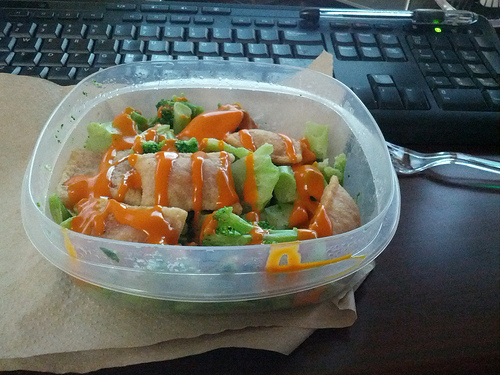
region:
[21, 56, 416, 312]
Plastic bowl filled with food.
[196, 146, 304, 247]
Pieces of broccoli in bowl.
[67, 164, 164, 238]
French dressing over salad.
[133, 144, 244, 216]
Dumplings in a bowl of salad.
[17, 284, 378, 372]
Edge of white napkin on desk.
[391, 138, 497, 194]
Clear plastic fork lying on desk.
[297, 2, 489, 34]
Pen lying on computer keyboard.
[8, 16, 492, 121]
Computer keyboard sitting on desk.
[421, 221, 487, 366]
A brown wood desk.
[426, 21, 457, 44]
Light on computer keyboard.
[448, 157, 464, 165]
a transparent fork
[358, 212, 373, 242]
edge of a food container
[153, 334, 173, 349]
part of a white tissue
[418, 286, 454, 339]
section of a wooden table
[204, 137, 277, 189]
food in a container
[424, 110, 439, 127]
edge of a key board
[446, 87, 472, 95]
key pad of a computer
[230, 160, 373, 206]
inside of a food container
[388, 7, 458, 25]
a pen on a key board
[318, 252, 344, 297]
bottom of a food container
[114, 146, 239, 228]
Orange sauce on top of food.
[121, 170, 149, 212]
Brown food under sauce.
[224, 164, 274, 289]
Broccoli mixed in with food.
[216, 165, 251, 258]
Broccoli is green in color.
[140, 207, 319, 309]
Food is in a clear container.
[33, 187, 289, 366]
Clear container is on napkin.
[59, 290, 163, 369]
Napkin under bowl is white.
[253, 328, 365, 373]
Napkin is on top of table.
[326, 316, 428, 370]
Table is brown in color.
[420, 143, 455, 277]
Disposable fork is on table.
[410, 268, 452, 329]
part of a black table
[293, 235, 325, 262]
edge of a food container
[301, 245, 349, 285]
side of a container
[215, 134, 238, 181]
food on a container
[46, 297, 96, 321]
a white piece of tissue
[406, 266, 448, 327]
part of a lack table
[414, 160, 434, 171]
a transparent fork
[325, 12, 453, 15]
a pen on a key board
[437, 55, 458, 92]
section of a key board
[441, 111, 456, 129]
edge of the key board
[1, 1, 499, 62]
a black computer keyboard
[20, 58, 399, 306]
a vegetable salad in a clear bowl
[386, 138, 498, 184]
a clear fork made of plastic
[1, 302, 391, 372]
a beige color napkin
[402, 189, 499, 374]
a dark burgundy wood desk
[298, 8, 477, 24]
a pen laying on top of the keyboard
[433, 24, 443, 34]
the green power light of the keyboard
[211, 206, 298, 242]
broccoli pieces in the salad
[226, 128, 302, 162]
a dumpling with a dressing on it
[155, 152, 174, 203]
an orange color French dressing